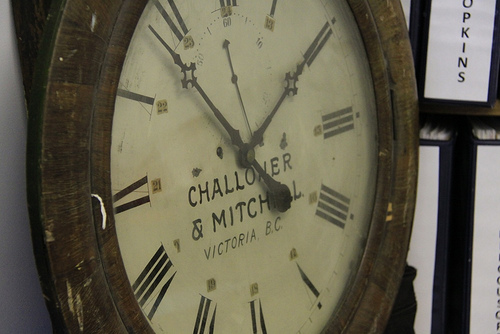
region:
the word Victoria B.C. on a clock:
[192, 211, 291, 261]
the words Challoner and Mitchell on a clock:
[168, 149, 316, 244]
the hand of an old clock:
[138, 19, 295, 210]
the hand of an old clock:
[220, 22, 342, 162]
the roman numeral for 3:
[311, 102, 374, 144]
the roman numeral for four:
[304, 176, 361, 240]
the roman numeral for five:
[289, 252, 336, 316]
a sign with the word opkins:
[419, 0, 492, 107]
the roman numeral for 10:
[110, 72, 157, 129]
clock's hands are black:
[154, 23, 336, 233]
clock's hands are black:
[140, 22, 340, 213]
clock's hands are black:
[150, 15, 387, 277]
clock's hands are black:
[121, 11, 386, 284]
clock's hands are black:
[142, 22, 354, 243]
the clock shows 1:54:
[124, 13, 342, 221]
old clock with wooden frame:
[47, 0, 421, 330]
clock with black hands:
[170, 21, 329, 216]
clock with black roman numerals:
[94, 0, 389, 327]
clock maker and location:
[176, 148, 309, 263]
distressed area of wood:
[52, 175, 99, 327]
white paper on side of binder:
[414, 0, 493, 106]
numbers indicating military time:
[146, 169, 171, 198]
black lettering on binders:
[432, 0, 484, 98]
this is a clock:
[51, 0, 416, 326]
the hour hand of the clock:
[262, 64, 304, 131]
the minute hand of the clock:
[181, 60, 261, 132]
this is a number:
[106, 173, 158, 216]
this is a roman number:
[119, 65, 164, 110]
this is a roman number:
[129, 235, 176, 317]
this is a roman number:
[201, 297, 234, 332]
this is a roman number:
[252, 300, 272, 327]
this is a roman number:
[306, 183, 363, 236]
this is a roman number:
[319, 103, 356, 141]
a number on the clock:
[284, 251, 339, 310]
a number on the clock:
[299, 170, 356, 238]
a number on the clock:
[314, 93, 360, 142]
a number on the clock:
[108, 171, 168, 235]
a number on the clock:
[110, 80, 172, 132]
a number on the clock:
[119, 240, 179, 322]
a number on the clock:
[181, 282, 226, 332]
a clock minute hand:
[149, 24, 293, 209]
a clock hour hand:
[242, 48, 314, 166]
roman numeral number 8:
[128, 243, 178, 316]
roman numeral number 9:
[111, 174, 150, 214]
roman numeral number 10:
[116, 78, 159, 120]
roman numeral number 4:
[311, 184, 353, 229]